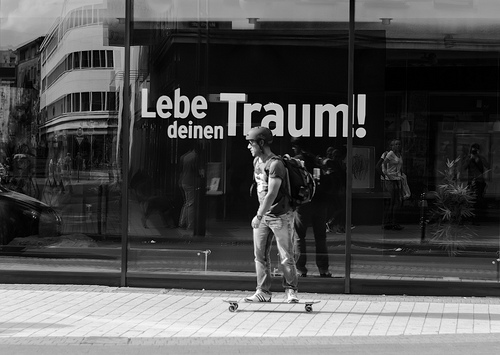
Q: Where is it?
A: This is at the road.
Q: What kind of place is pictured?
A: It is a road.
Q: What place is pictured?
A: It is a road.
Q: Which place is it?
A: It is a road.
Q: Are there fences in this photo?
A: No, there are no fences.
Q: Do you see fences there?
A: No, there are no fences.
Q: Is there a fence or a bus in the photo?
A: No, there are no fences or buses.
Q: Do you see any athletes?
A: No, there are no athletes.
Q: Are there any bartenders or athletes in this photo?
A: No, there are no athletes or bartenders.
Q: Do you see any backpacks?
A: Yes, there is a backpack.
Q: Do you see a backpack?
A: Yes, there is a backpack.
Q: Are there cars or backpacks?
A: Yes, there is a backpack.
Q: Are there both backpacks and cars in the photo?
A: Yes, there are both a backpack and a car.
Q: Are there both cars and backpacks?
A: Yes, there are both a backpack and a car.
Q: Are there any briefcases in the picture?
A: No, there are no briefcases.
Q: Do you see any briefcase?
A: No, there are no briefcases.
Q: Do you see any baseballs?
A: No, there are no baseballs.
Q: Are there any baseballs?
A: No, there are no baseballs.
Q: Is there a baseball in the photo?
A: No, there are no baseballs.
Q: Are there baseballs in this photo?
A: No, there are no baseballs.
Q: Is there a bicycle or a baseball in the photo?
A: No, there are no baseballs or bicycles.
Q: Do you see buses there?
A: No, there are no buses.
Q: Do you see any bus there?
A: No, there are no buses.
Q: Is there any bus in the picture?
A: No, there are no buses.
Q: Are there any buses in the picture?
A: No, there are no buses.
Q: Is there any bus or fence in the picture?
A: No, there are no buses or fences.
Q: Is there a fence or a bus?
A: No, there are no buses or fences.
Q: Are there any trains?
A: No, there are no trains.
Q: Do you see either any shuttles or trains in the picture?
A: No, there are no trains or shuttles.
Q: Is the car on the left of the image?
A: Yes, the car is on the left of the image.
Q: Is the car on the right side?
A: No, the car is on the left of the image.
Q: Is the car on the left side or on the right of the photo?
A: The car is on the left of the image.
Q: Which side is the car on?
A: The car is on the left of the image.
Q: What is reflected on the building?
A: The car is reflected on the building.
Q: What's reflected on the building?
A: The car is reflected on the building.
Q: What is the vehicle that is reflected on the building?
A: The vehicle is a car.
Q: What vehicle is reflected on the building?
A: The vehicle is a car.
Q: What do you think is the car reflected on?
A: The car is reflected on the building.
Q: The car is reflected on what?
A: The car is reflected on the building.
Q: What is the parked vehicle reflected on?
A: The car is reflected on the building.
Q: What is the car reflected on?
A: The car is reflected on the building.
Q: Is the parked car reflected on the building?
A: Yes, the car is reflected on the building.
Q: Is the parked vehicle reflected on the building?
A: Yes, the car is reflected on the building.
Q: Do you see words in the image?
A: Yes, there are words.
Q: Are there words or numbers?
A: Yes, there are words.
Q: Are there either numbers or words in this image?
A: Yes, there are words.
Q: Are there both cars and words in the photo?
A: Yes, there are both words and a car.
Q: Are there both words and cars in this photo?
A: Yes, there are both words and a car.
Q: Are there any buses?
A: No, there are no buses.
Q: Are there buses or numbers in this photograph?
A: No, there are no buses or numbers.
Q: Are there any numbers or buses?
A: No, there are no buses or numbers.